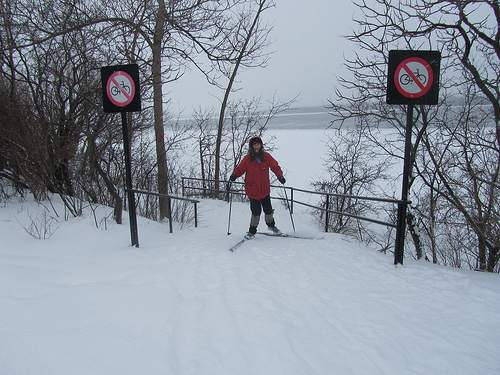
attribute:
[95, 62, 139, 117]
sign — black, white, red, cold, whtie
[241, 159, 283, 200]
jacket — red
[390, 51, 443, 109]
sign — red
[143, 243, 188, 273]
snow — white, cold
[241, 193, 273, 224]
pants — black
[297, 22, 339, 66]
sky — cloudy